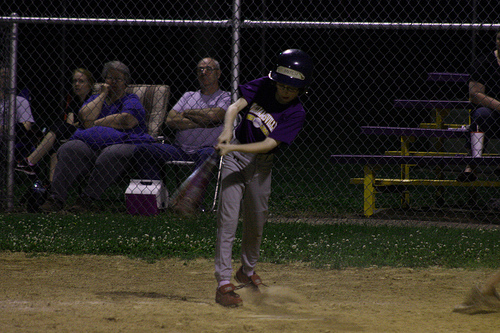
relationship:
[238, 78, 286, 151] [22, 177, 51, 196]
boy hitting ball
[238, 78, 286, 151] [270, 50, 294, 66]
boy wearing helmet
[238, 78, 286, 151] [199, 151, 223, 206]
boy holding bat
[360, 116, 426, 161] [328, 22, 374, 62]
bleachers are next to fence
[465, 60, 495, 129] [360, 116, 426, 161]
man sitting on bleachers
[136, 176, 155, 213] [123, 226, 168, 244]
cooler on grass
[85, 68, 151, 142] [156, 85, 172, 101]
woman sitting on chair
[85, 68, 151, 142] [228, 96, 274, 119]
woman wearing shirt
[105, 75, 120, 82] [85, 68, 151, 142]
glasses are on woman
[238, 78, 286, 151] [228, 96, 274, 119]
boy wearing shirt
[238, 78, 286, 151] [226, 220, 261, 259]
boy wearing pants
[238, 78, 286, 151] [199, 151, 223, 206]
boy swinging a bat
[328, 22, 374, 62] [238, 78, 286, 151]
fence behind boy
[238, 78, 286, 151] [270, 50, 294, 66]
boy wears helmet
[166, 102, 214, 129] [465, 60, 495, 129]
arms of man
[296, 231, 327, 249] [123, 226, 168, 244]
flowers are on grass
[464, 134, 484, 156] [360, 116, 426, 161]
cup on bleachers